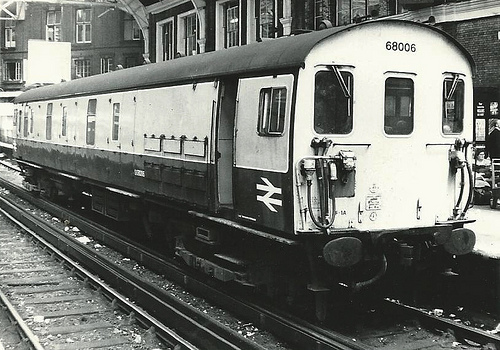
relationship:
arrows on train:
[246, 169, 297, 218] [11, 17, 479, 322]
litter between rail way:
[28, 204, 102, 254] [2, 158, 361, 348]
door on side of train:
[207, 80, 242, 210] [6, 22, 480, 279]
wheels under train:
[213, 252, 274, 302] [11, 17, 479, 322]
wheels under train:
[165, 225, 204, 280] [11, 17, 479, 322]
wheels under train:
[35, 181, 55, 203] [11, 17, 479, 322]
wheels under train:
[21, 171, 36, 191] [11, 17, 479, 322]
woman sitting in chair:
[466, 145, 495, 202] [470, 165, 495, 204]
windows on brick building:
[36, 0, 99, 52] [21, 7, 121, 70]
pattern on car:
[251, 171, 288, 211] [12, 21, 474, 281]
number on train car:
[378, 36, 427, 57] [11, 17, 473, 328]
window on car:
[314, 71, 352, 140] [20, 57, 498, 307]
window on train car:
[378, 72, 417, 137] [21, 14, 478, 299]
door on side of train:
[151, 70, 261, 191] [74, 63, 479, 287]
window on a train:
[440, 72, 468, 132] [11, 17, 479, 322]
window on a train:
[314, 62, 356, 135] [11, 17, 479, 322]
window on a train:
[245, 87, 315, 128] [114, 14, 499, 285]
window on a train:
[112, 102, 119, 139] [11, 17, 479, 322]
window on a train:
[60, 104, 68, 135] [6, 22, 480, 279]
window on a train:
[44, 103, 52, 138] [11, 17, 479, 322]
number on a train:
[386, 39, 417, 51] [11, 17, 479, 322]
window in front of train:
[314, 62, 356, 135] [11, 17, 479, 322]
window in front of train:
[381, 69, 415, 139] [11, 17, 479, 322]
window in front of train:
[440, 72, 468, 132] [11, 17, 479, 322]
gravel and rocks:
[55, 131, 285, 337] [237, 257, 472, 334]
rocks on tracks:
[237, 257, 472, 334] [10, 190, 414, 348]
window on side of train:
[112, 102, 119, 139] [11, 17, 479, 322]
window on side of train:
[85, 97, 95, 144] [11, 17, 479, 322]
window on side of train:
[60, 104, 68, 135] [11, 17, 479, 322]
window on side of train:
[46, 102, 52, 139] [11, 17, 479, 322]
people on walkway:
[473, 117, 498, 180] [464, 200, 498, 242]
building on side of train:
[111, 0, 498, 210] [11, 17, 479, 322]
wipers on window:
[330, 62, 352, 96] [314, 62, 356, 135]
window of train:
[314, 62, 356, 135] [4, 19, 481, 240]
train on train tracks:
[15, 36, 483, 218] [20, 214, 454, 346]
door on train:
[210, 64, 242, 222] [6, 22, 480, 279]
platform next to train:
[459, 201, 499, 263] [11, 17, 479, 322]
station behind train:
[115, 2, 499, 206] [11, 17, 479, 322]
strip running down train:
[2, 139, 291, 245] [11, 17, 479, 322]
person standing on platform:
[483, 117, 496, 187] [470, 193, 484, 229]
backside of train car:
[294, 18, 474, 234] [11, 17, 473, 328]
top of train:
[17, 19, 473, 104] [14, 15, 479, 98]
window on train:
[82, 98, 95, 148] [11, 17, 479, 322]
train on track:
[99, 70, 475, 225] [2, 159, 499, 349]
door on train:
[213, 72, 243, 217] [11, 17, 479, 322]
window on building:
[174, 10, 206, 63] [136, 0, 212, 65]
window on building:
[153, 12, 175, 67] [136, 0, 212, 65]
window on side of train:
[41, 104, 56, 142] [11, 17, 479, 322]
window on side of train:
[82, 98, 95, 148] [11, 17, 479, 322]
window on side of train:
[22, 103, 31, 140] [11, 17, 479, 322]